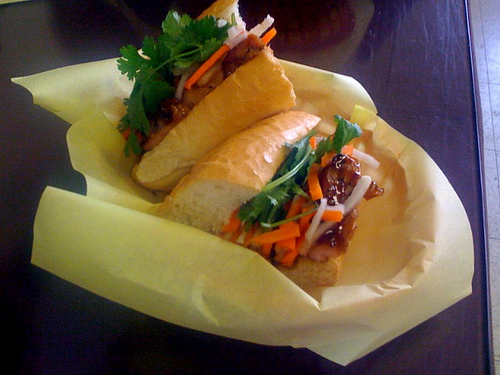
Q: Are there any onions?
A: Yes, there are onions.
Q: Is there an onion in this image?
A: Yes, there are onions.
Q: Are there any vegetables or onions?
A: Yes, there are onions.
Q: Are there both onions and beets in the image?
A: No, there are onions but no beets.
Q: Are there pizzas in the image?
A: No, there are no pizzas.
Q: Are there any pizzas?
A: No, there are no pizzas.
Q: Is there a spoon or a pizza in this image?
A: No, there are no pizzas or spoons.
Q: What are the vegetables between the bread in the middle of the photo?
A: The vegetables are onions.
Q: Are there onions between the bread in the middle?
A: Yes, there are onions between the bread.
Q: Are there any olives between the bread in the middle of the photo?
A: No, there are onions between the bread.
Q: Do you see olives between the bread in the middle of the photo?
A: No, there are onions between the bread.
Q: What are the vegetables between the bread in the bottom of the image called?
A: The vegetables are onions.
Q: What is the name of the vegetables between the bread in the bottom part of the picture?
A: The vegetables are onions.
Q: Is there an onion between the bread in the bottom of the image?
A: Yes, there are onions between the bread.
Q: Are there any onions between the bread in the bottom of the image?
A: Yes, there are onions between the bread.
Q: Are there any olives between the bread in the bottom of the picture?
A: No, there are onions between the bread.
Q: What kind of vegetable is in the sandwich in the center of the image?
A: The vegetables are onions.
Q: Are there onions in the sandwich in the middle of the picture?
A: Yes, there are onions in the sandwich.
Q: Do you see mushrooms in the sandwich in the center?
A: No, there are onions in the sandwich.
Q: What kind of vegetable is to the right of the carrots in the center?
A: The vegetables are onions.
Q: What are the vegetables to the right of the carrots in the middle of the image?
A: The vegetables are onions.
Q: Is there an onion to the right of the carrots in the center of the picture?
A: Yes, there are onions to the right of the carrots.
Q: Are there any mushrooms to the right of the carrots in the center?
A: No, there are onions to the right of the carrots.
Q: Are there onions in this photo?
A: Yes, there are onions.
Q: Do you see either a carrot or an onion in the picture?
A: Yes, there are onions.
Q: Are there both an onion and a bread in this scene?
A: Yes, there are both an onion and a bread.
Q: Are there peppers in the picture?
A: No, there are no peppers.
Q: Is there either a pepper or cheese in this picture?
A: No, there are no peppers or cheese.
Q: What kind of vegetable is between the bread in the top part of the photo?
A: The vegetables are onions.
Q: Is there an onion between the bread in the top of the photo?
A: Yes, there are onions between the bread.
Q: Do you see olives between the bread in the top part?
A: No, there are onions between the bread.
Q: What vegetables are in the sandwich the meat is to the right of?
A: The vegetables are onions.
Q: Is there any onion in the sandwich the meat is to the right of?
A: Yes, there are onions in the sandwich.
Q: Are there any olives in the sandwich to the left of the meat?
A: No, there are onions in the sandwich.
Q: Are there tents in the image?
A: No, there are no tents.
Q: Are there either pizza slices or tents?
A: No, there are no tents or pizza slices.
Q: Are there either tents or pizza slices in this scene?
A: No, there are no tents or pizza slices.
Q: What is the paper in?
A: The paper is in the bowl.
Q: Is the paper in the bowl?
A: Yes, the paper is in the bowl.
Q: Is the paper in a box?
A: No, the paper is in the bowl.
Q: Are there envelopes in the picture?
A: No, there are no envelopes.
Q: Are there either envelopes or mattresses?
A: No, there are no envelopes or mattresses.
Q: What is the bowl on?
A: The bowl is on the table.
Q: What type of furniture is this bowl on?
A: The bowl is on the table.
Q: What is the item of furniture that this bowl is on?
A: The piece of furniture is a table.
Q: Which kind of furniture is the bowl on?
A: The bowl is on the table.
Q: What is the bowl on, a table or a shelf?
A: The bowl is on a table.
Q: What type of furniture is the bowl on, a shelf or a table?
A: The bowl is on a table.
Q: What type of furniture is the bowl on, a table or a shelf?
A: The bowl is on a table.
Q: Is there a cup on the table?
A: No, there is a bowl on the table.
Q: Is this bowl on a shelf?
A: No, the bowl is on the table.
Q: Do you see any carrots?
A: Yes, there are carrots.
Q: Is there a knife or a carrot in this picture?
A: Yes, there are carrots.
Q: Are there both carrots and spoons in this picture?
A: No, there are carrots but no spoons.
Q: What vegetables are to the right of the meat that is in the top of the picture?
A: The vegetables are carrots.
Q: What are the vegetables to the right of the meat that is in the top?
A: The vegetables are carrots.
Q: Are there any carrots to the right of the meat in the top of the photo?
A: Yes, there are carrots to the right of the meat.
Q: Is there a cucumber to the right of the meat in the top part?
A: No, there are carrots to the right of the meat.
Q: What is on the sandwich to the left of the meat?
A: The carrots are on the sandwich.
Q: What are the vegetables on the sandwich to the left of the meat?
A: The vegetables are carrots.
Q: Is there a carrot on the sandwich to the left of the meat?
A: Yes, there are carrots on the sandwich.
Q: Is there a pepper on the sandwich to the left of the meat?
A: No, there are carrots on the sandwich.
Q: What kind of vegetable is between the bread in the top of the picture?
A: The vegetables are carrots.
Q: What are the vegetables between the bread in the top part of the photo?
A: The vegetables are carrots.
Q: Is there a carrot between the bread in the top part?
A: Yes, there are carrots between the bread.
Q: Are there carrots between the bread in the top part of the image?
A: Yes, there are carrots between the bread.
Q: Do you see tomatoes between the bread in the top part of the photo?
A: No, there are carrots between the bread.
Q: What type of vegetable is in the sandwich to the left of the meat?
A: The vegetables are carrots.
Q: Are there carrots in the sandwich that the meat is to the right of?
A: Yes, there are carrots in the sandwich.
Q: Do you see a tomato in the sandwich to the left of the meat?
A: No, there are carrots in the sandwich.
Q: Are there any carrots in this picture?
A: Yes, there are carrots.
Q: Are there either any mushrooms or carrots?
A: Yes, there are carrots.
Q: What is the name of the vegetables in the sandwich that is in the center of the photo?
A: The vegetables are carrots.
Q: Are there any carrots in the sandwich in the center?
A: Yes, there are carrots in the sandwich.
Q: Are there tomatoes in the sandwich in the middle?
A: No, there are carrots in the sandwich.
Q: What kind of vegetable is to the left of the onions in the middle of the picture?
A: The vegetables are carrots.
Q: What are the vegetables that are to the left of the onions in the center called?
A: The vegetables are carrots.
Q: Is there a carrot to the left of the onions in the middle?
A: Yes, there are carrots to the left of the onions.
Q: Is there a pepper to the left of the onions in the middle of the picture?
A: No, there are carrots to the left of the onions.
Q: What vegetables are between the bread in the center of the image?
A: The vegetables are carrots.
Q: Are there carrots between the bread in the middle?
A: Yes, there are carrots between the bread.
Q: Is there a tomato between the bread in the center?
A: No, there are carrots between the bread.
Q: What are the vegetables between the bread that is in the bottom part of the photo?
A: The vegetables are carrots.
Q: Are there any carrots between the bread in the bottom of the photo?
A: Yes, there are carrots between the bread.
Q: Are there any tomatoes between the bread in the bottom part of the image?
A: No, there are carrots between the bread.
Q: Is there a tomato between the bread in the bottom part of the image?
A: No, there are carrots between the bread.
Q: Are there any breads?
A: Yes, there is a bread.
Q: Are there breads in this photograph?
A: Yes, there is a bread.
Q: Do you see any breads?
A: Yes, there is a bread.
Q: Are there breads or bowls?
A: Yes, there is a bread.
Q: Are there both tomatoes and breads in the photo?
A: No, there is a bread but no tomatoes.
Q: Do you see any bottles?
A: No, there are no bottles.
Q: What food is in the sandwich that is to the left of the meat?
A: The food is a bread.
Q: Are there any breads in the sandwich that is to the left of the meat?
A: Yes, there is a bread in the sandwich.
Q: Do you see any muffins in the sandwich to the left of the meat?
A: No, there is a bread in the sandwich.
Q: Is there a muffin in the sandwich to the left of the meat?
A: No, there is a bread in the sandwich.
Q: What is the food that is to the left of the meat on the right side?
A: The food is a bread.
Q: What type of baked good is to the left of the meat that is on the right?
A: The food is a bread.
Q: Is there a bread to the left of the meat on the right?
A: Yes, there is a bread to the left of the meat.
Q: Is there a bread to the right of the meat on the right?
A: No, the bread is to the left of the meat.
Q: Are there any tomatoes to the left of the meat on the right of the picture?
A: No, there is a bread to the left of the meat.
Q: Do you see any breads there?
A: Yes, there is a bread.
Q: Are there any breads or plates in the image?
A: Yes, there is a bread.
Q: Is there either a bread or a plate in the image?
A: Yes, there is a bread.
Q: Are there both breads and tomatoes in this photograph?
A: No, there is a bread but no tomatoes.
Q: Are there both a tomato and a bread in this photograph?
A: No, there is a bread but no tomatoes.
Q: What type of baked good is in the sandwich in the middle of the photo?
A: The food is a bread.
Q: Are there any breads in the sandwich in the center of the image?
A: Yes, there is a bread in the sandwich.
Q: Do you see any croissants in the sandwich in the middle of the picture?
A: No, there is a bread in the sandwich.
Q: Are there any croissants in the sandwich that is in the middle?
A: No, there is a bread in the sandwich.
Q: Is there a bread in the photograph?
A: Yes, there is a bread.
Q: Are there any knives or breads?
A: Yes, there is a bread.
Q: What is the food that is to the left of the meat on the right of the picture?
A: The food is a bread.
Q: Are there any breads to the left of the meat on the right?
A: Yes, there is a bread to the left of the meat.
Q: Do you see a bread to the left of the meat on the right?
A: Yes, there is a bread to the left of the meat.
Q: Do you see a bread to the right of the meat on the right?
A: No, the bread is to the left of the meat.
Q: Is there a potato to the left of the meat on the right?
A: No, there is a bread to the left of the meat.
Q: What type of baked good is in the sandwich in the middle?
A: The food is a bread.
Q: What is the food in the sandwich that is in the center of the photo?
A: The food is a bread.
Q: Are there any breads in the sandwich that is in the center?
A: Yes, there is a bread in the sandwich.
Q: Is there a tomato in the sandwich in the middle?
A: No, there is a bread in the sandwich.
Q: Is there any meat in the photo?
A: Yes, there is meat.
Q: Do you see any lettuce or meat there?
A: Yes, there is meat.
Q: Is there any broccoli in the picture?
A: No, there is no broccoli.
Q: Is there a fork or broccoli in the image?
A: No, there are no broccoli or forks.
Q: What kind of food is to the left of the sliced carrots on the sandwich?
A: The food is meat.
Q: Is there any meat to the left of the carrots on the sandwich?
A: Yes, there is meat to the left of the carrots.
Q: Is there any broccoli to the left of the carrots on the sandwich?
A: No, there is meat to the left of the carrots.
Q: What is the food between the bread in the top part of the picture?
A: The food is meat.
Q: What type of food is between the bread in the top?
A: The food is meat.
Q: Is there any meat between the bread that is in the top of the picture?
A: Yes, there is meat between the bread.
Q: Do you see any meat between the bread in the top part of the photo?
A: Yes, there is meat between the bread.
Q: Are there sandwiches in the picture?
A: Yes, there is a sandwich.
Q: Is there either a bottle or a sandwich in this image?
A: Yes, there is a sandwich.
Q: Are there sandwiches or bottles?
A: Yes, there is a sandwich.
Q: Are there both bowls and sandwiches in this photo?
A: Yes, there are both a sandwich and a bowl.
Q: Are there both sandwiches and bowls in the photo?
A: Yes, there are both a sandwich and a bowl.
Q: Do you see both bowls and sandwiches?
A: Yes, there are both a sandwich and a bowl.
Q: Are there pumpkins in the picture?
A: No, there are no pumpkins.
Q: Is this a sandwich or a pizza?
A: This is a sandwich.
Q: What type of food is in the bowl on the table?
A: The food is a sandwich.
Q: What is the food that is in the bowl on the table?
A: The food is a sandwich.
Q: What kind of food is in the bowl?
A: The food is a sandwich.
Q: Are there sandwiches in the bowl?
A: Yes, there is a sandwich in the bowl.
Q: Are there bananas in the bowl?
A: No, there is a sandwich in the bowl.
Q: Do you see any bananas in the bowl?
A: No, there is a sandwich in the bowl.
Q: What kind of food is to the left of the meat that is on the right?
A: The food is a sandwich.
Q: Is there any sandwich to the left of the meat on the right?
A: Yes, there is a sandwich to the left of the meat.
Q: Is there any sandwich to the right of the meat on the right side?
A: No, the sandwich is to the left of the meat.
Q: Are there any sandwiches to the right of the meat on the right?
A: No, the sandwich is to the left of the meat.